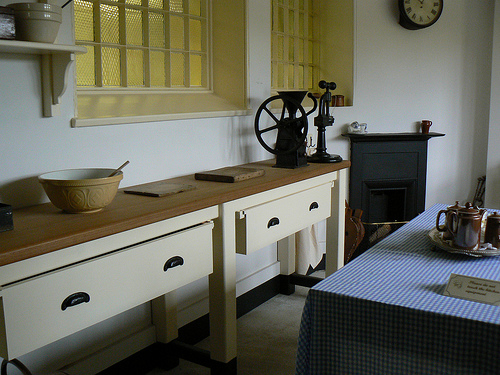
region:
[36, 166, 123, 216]
A tan colored bowl with a pretty design on the outside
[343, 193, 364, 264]
A fireplace fan sitting in a corner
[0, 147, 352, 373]
A buffet with a wooden top and two drawers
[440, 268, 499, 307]
A name plate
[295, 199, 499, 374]
A blue and white checked tablecloth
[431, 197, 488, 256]
Copper and silver plated cream and sugar holder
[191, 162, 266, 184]
A cutting board on top of a buffet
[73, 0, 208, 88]
A window with many panes and a screen behind it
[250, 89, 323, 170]
A black coffee grinder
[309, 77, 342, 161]
A black apple press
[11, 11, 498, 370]
Old fashioned kitchen.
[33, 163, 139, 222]
Mixing bowel with utensil.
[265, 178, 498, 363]
Table with table cloth.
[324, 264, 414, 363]
Cloth with blue and white checked pattern.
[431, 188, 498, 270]
multi-colored pottery on dish.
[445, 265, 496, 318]
Place card with text.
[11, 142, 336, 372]
Side table with half-moon knobs on drawers.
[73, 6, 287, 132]
Recessed window with cream frame and pane-frames.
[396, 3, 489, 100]
Round clock on white wall.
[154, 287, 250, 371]
Column-like legs with black bottoms.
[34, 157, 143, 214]
large tan and white bowl with wooden spoon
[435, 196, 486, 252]
dark brown pewter coffee pot with lid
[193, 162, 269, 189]
large dark brown cutting board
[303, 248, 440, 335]
portion of blue and white patterned table cloth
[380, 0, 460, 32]
portion of black clock with white face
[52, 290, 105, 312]
intricate black brass table knob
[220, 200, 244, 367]
long white table leg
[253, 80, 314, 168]
large black object with circular wheel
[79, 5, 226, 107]
yellow pane square window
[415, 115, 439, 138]
small brown coffee cup with handle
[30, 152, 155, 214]
A mixing bowl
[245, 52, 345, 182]
a food preperation device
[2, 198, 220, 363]
a drawer under a counter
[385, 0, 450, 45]
a clock on the wall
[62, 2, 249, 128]
a kitchen window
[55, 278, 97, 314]
A knob on a drawer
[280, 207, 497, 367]
A kitchen table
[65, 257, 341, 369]
a kitchen floor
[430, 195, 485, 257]
a pitcher for liquids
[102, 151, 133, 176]
a spoon handle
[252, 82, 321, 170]
meat grinder from another century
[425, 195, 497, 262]
silver that needs polishing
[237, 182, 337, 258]
a drawer with two handles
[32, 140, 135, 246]
a bowl oddly stored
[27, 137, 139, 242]
a bowl on a countertop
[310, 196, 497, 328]
blue and white checked tablecloth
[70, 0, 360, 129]
two windows with wire mesh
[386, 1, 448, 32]
an analog clock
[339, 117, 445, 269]
a really old fireplace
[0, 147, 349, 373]
furniture for storage and work tops